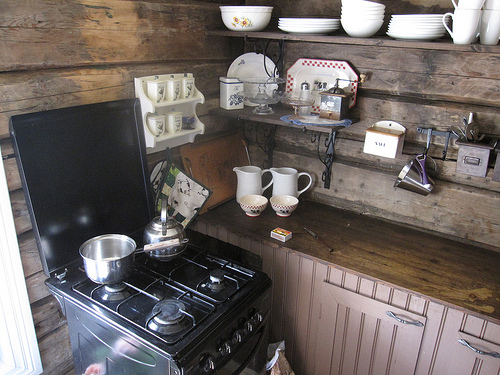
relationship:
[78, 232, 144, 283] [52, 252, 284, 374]
pan on stove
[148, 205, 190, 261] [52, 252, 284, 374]
kettle on stove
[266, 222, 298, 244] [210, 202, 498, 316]
matches on counter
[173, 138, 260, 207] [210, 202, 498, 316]
tray on counter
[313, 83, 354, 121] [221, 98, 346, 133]
sifter on shelf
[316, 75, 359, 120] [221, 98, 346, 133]
coffee grinder on shelf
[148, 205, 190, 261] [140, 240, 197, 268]
kettle on burner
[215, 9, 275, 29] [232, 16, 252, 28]
bowl has flowers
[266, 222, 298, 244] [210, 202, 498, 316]
matchbox on counter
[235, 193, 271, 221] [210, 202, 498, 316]
tea cup on counter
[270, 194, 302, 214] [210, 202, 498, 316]
tea cup on counter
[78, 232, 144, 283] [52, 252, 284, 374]
pot on stove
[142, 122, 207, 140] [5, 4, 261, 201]
shelf on wall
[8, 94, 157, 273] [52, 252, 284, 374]
lid on stove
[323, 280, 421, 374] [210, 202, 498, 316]
cabinet door below counter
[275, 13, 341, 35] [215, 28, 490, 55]
dishes on shelf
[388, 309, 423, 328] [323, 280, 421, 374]
handle for door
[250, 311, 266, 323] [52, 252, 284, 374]
knob on stove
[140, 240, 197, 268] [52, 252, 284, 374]
burner on stove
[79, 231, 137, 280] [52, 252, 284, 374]
pot on stove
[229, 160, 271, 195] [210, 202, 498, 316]
pitcher on counter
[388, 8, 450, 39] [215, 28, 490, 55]
plates on shelf